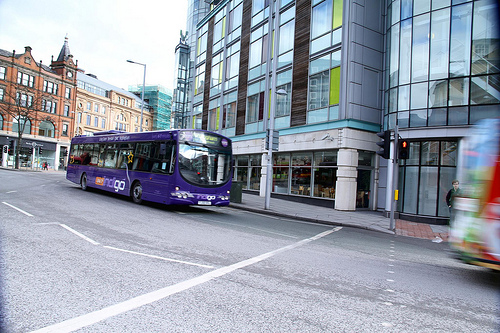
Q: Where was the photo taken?
A: It was taken at the road.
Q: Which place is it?
A: It is a road.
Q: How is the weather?
A: It is cloudy.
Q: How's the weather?
A: It is cloudy.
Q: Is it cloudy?
A: Yes, it is cloudy.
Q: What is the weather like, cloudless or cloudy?
A: It is cloudy.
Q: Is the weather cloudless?
A: No, it is cloudy.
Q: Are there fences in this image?
A: No, there are no fences.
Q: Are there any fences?
A: No, there are no fences.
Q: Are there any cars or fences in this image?
A: No, there are no fences or cars.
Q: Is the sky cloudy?
A: Yes, the sky is cloudy.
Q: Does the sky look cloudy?
A: Yes, the sky is cloudy.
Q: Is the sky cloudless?
A: No, the sky is cloudy.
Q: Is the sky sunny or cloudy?
A: The sky is cloudy.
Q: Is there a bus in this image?
A: Yes, there is a bus.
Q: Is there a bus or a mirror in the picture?
A: Yes, there is a bus.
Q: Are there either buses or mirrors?
A: Yes, there is a bus.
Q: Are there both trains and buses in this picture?
A: No, there is a bus but no trains.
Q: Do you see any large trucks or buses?
A: Yes, there is a large bus.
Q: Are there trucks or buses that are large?
A: Yes, the bus is large.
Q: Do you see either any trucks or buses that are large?
A: Yes, the bus is large.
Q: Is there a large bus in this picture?
A: Yes, there is a large bus.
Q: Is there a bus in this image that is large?
A: Yes, there is a bus that is large.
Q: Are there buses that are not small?
A: Yes, there is a large bus.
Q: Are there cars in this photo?
A: No, there are no cars.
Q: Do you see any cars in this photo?
A: No, there are no cars.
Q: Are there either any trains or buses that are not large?
A: No, there is a bus but it is large.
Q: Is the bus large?
A: Yes, the bus is large.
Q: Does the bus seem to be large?
A: Yes, the bus is large.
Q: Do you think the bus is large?
A: Yes, the bus is large.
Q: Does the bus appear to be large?
A: Yes, the bus is large.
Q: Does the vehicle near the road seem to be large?
A: Yes, the bus is large.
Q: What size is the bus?
A: The bus is large.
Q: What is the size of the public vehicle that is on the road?
A: The bus is large.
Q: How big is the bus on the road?
A: The bus is large.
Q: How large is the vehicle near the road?
A: The bus is large.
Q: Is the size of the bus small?
A: No, the bus is large.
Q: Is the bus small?
A: No, the bus is large.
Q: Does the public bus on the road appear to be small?
A: No, the bus is large.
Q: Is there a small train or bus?
A: No, there is a bus but it is large.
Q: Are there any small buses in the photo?
A: No, there is a bus but it is large.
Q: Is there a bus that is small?
A: No, there is a bus but it is large.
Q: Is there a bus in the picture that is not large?
A: No, there is a bus but it is large.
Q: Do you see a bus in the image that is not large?
A: No, there is a bus but it is large.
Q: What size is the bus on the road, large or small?
A: The bus is large.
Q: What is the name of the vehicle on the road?
A: The vehicle is a bus.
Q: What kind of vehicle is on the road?
A: The vehicle is a bus.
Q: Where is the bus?
A: The bus is on the road.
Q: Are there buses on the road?
A: Yes, there is a bus on the road.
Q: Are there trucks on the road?
A: No, there is a bus on the road.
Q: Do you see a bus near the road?
A: Yes, there is a bus near the road.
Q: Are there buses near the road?
A: Yes, there is a bus near the road.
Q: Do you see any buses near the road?
A: Yes, there is a bus near the road.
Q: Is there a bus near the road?
A: Yes, there is a bus near the road.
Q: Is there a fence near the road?
A: No, there is a bus near the road.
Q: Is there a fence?
A: No, there are no fences.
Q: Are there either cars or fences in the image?
A: No, there are no fences or cars.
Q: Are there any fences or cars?
A: No, there are no fences or cars.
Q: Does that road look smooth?
A: Yes, the road is smooth.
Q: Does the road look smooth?
A: Yes, the road is smooth.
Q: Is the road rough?
A: No, the road is smooth.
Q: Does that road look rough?
A: No, the road is smooth.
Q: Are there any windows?
A: Yes, there is a window.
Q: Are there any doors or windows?
A: Yes, there is a window.